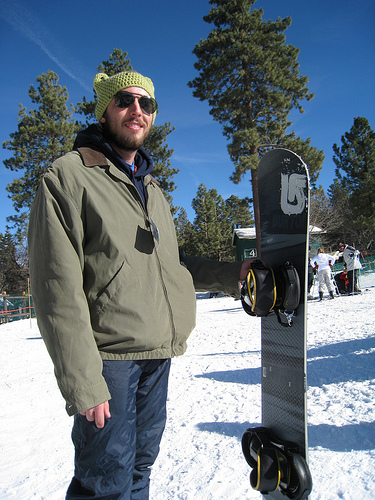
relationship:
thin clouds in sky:
[2, 2, 374, 265] [0, 0, 375, 268]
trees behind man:
[0, 0, 374, 301] [29, 72, 257, 498]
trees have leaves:
[0, 0, 374, 301] [2, 1, 373, 262]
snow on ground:
[0, 270, 374, 499] [1, 274, 374, 499]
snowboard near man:
[239, 147, 312, 499] [29, 72, 257, 498]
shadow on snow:
[23, 290, 374, 453] [0, 270, 374, 499]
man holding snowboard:
[29, 72, 257, 498] [239, 147, 312, 499]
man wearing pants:
[31, 72, 258, 498] [67, 359, 172, 499]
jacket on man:
[28, 145, 197, 416] [29, 72, 257, 498]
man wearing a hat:
[31, 72, 258, 498] [94, 72, 157, 127]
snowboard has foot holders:
[239, 147, 312, 499] [238, 259, 313, 499]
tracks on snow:
[0, 272, 375, 499] [0, 270, 374, 499]